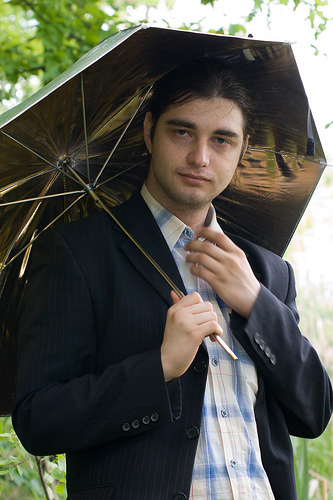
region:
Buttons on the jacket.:
[109, 409, 173, 437]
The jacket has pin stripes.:
[65, 269, 161, 464]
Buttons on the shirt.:
[215, 403, 243, 468]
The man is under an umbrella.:
[19, 83, 326, 237]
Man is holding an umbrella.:
[53, 37, 329, 247]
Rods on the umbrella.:
[23, 142, 125, 204]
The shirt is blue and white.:
[200, 361, 260, 491]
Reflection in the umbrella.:
[264, 90, 320, 188]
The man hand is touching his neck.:
[161, 232, 217, 280]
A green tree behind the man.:
[18, 1, 148, 56]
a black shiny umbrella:
[2, 23, 326, 418]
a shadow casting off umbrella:
[231, 117, 328, 201]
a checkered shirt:
[140, 185, 277, 499]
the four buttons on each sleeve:
[119, 329, 278, 436]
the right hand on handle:
[161, 287, 239, 381]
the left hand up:
[184, 223, 262, 311]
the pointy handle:
[207, 336, 240, 362]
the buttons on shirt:
[182, 225, 239, 466]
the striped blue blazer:
[11, 189, 332, 497]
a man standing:
[0, 20, 332, 499]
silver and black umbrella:
[1, 25, 331, 417]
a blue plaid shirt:
[139, 184, 272, 499]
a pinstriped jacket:
[10, 188, 329, 498]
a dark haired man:
[13, 57, 316, 498]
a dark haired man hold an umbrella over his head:
[3, 23, 332, 497]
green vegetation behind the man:
[4, 412, 65, 499]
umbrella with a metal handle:
[2, 20, 332, 362]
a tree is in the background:
[1, 0, 328, 113]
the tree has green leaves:
[0, 2, 331, 108]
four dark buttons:
[120, 411, 160, 433]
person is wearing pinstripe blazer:
[11, 180, 332, 498]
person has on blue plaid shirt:
[134, 183, 276, 498]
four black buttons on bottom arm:
[121, 410, 160, 432]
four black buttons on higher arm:
[251, 331, 279, 365]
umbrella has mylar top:
[2, 22, 330, 419]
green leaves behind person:
[1, 1, 331, 498]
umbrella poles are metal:
[2, 26, 332, 407]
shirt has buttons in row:
[211, 358, 236, 467]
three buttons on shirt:
[211, 357, 238, 468]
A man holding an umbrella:
[1, 16, 329, 498]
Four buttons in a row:
[118, 408, 160, 433]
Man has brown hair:
[136, 50, 254, 206]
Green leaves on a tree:
[2, 2, 331, 103]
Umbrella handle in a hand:
[155, 279, 241, 377]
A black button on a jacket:
[178, 415, 204, 444]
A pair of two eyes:
[167, 122, 234, 148]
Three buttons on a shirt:
[206, 354, 244, 472]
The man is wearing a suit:
[8, 49, 331, 497]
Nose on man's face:
[183, 138, 214, 172]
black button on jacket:
[148, 411, 158, 422]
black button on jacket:
[129, 416, 140, 429]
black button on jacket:
[120, 420, 130, 431]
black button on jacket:
[184, 424, 197, 438]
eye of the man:
[195, 118, 253, 158]